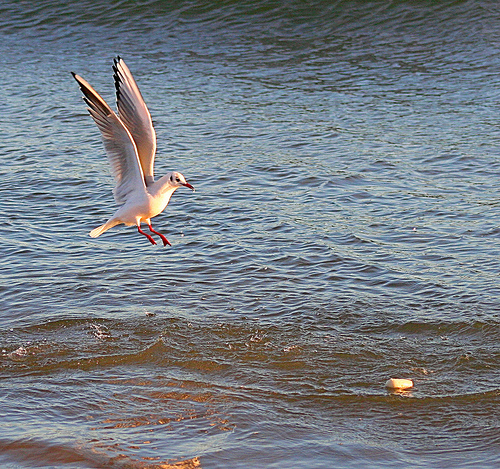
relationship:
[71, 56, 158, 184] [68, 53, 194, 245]
wings of bird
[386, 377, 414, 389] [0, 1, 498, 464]
chunk on water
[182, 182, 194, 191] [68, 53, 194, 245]
bill on bird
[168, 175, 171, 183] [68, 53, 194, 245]
spot on bird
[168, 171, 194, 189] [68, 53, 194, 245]
head on bird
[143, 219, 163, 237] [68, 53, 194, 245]
left leg of bird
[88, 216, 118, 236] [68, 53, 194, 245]
tail of bird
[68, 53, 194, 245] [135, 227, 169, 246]
bird with legs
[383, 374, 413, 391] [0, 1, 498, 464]
chunk in water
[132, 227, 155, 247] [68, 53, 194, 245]
leg of a bird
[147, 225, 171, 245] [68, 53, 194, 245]
left leg of a bird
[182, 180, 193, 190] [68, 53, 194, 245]
beak on a bird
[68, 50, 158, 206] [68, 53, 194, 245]
wings of a bird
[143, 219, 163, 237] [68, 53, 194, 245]
left leg of a bird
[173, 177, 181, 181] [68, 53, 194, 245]
eye of a bird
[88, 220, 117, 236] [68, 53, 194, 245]
tail feathers on a bird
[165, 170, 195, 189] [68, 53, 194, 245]
head of a bird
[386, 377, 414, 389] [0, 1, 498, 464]
chunk floating in water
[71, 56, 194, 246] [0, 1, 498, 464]
bird flying over water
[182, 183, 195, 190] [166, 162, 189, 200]
beak sticking off face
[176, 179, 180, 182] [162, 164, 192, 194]
eye on side of face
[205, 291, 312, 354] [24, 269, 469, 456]
ripples in water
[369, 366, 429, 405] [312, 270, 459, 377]
something floating in water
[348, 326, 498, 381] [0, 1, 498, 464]
ripple in water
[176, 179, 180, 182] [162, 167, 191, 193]
eye side of head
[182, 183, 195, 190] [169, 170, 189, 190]
beak sticking off of face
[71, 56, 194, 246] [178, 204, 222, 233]
bird flying through air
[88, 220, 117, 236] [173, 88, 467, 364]
tail feathers in water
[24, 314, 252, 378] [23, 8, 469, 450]
waves in water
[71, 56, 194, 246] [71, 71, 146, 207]
bird has wings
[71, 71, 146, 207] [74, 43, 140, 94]
wings are up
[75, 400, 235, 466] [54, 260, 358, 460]
light reflecting off water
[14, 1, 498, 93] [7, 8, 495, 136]
shadow in back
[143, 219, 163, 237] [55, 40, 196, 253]
left leg on bird